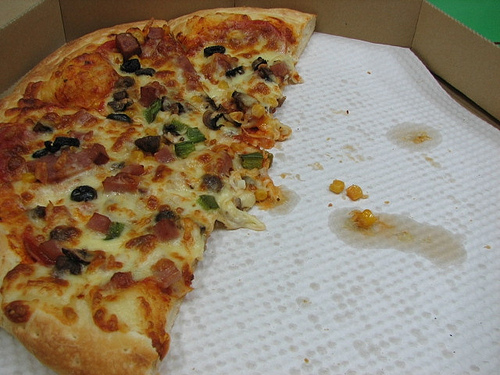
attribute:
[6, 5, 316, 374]
pizza half — half gone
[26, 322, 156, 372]
crust — brown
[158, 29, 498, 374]
paper — whiter, lining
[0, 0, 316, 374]
pizza — half eaten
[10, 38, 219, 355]
pizza — cooked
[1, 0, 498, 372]
box — cardboard, brown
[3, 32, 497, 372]
packaging — paper, under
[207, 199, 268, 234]
cheese — falling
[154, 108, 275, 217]
peppers — green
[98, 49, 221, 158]
kernals — corn